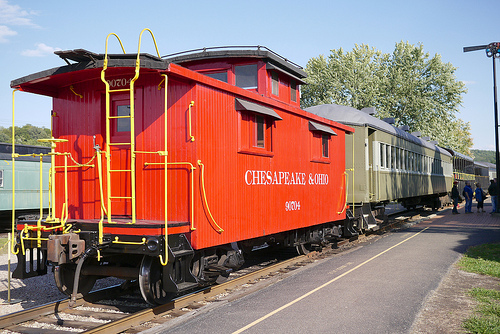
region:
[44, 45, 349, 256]
orange caboose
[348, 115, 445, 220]
green train car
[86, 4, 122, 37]
white clouds in blue sky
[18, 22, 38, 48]
white clouds in blue sky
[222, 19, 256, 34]
white clouds in blue sky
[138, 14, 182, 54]
white clouds in blue sky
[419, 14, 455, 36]
white clouds in blue sky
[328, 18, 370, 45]
white clouds in blue sky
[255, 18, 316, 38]
white clouds in blue sky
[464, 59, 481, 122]
white clouds in blue sky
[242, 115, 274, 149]
window on a train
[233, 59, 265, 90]
window on a train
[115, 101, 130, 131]
window on a train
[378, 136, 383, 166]
window on a train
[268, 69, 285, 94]
window on a train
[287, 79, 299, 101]
window on a train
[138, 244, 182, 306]
wheel on a train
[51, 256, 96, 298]
wheel on a train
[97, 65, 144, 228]
yellow ladder on a train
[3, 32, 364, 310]
red car on a train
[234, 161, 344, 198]
name on the train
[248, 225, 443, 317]
a white line on the road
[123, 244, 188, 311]
wheel of the train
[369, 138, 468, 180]
a windows in train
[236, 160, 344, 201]
white text in train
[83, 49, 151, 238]
a ladder on back o ftrain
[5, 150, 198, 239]
a supportive iron stand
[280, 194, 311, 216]
number of the train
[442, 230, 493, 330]
side part of grass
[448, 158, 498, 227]
a group of people standing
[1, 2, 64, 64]
White clouds in the sky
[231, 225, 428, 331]
White line on the pavement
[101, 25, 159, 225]
A ladder is yellow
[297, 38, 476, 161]
Green leaves on a tree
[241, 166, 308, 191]
"CHESAPEAKE" written on side of train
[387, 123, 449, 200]
Shadows on a train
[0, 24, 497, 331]
A train on train tracks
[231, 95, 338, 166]
Two windows of side of train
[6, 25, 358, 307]
A red train car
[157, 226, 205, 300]
Two steps to the train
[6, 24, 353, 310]
a red caboose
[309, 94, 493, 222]
passenger cars on a train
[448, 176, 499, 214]
people standing near a train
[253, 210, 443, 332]
a walking path near a train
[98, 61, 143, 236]
yellow ladder on a caboose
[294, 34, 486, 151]
tree beyond the train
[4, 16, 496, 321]
train with a caboose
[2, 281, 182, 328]
train tracks on the ground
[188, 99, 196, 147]
a yellow handle on a caboose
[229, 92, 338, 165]
windows on a caboose